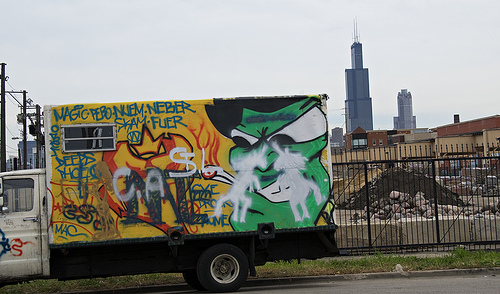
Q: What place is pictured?
A: It is a city.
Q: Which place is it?
A: It is a city.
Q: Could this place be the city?
A: Yes, it is the city.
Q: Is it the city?
A: Yes, it is the city.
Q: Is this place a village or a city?
A: It is a city.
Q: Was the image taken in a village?
A: No, the picture was taken in a city.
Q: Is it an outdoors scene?
A: Yes, it is outdoors.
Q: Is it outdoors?
A: Yes, it is outdoors.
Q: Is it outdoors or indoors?
A: It is outdoors.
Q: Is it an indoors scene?
A: No, it is outdoors.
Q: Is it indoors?
A: No, it is outdoors.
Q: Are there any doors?
A: Yes, there is a door.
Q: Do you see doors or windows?
A: Yes, there is a door.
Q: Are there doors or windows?
A: Yes, there is a door.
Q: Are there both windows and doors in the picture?
A: Yes, there are both a door and windows.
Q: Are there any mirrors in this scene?
A: No, there are no mirrors.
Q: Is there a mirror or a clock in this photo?
A: No, there are no mirrors or clocks.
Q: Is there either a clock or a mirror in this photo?
A: No, there are no mirrors or clocks.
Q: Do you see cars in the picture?
A: No, there are no cars.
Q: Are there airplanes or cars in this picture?
A: No, there are no cars or airplanes.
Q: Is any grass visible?
A: Yes, there is grass.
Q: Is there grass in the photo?
A: Yes, there is grass.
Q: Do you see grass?
A: Yes, there is grass.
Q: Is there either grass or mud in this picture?
A: Yes, there is grass.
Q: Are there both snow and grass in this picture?
A: No, there is grass but no snow.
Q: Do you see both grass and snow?
A: No, there is grass but no snow.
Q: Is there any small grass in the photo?
A: Yes, there is small grass.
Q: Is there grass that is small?
A: Yes, there is grass that is small.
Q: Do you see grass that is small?
A: Yes, there is grass that is small.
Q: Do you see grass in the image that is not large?
A: Yes, there is small grass.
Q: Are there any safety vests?
A: No, there are no safety vests.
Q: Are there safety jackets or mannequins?
A: No, there are no safety jackets or mannequins.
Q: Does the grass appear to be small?
A: Yes, the grass is small.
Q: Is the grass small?
A: Yes, the grass is small.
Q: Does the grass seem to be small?
A: Yes, the grass is small.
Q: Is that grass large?
A: No, the grass is small.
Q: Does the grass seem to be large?
A: No, the grass is small.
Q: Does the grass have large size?
A: No, the grass is small.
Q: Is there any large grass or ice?
A: No, there is grass but it is small.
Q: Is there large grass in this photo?
A: No, there is grass but it is small.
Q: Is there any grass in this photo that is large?
A: No, there is grass but it is small.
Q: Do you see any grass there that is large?
A: No, there is grass but it is small.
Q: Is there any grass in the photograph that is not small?
A: No, there is grass but it is small.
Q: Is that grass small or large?
A: The grass is small.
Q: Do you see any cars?
A: No, there are no cars.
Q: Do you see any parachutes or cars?
A: No, there are no cars or parachutes.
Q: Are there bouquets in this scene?
A: No, there are no bouquets.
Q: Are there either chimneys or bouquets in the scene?
A: No, there are no bouquets or chimneys.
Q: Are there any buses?
A: No, there are no buses.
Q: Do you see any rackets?
A: No, there are no rackets.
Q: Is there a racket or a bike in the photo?
A: No, there are no rackets or bikes.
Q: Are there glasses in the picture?
A: No, there are no glasses.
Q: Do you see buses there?
A: No, there are no buses.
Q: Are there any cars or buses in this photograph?
A: No, there are no buses or cars.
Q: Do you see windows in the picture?
A: Yes, there is a window.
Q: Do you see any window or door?
A: Yes, there is a window.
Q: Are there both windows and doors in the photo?
A: Yes, there are both a window and a door.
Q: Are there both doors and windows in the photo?
A: Yes, there are both a window and a door.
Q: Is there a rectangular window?
A: Yes, there is a rectangular window.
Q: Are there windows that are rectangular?
A: Yes, there is a window that is rectangular.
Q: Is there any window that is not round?
A: Yes, there is a rectangular window.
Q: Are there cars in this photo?
A: No, there are no cars.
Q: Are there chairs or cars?
A: No, there are no cars or chairs.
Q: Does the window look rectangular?
A: Yes, the window is rectangular.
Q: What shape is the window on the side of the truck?
A: The window is rectangular.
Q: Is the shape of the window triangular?
A: No, the window is rectangular.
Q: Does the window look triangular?
A: No, the window is rectangular.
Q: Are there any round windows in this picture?
A: No, there is a window but it is rectangular.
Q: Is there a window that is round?
A: No, there is a window but it is rectangular.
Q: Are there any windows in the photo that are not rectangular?
A: No, there is a window but it is rectangular.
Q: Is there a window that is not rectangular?
A: No, there is a window but it is rectangular.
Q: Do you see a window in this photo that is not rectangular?
A: No, there is a window but it is rectangular.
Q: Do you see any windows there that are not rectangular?
A: No, there is a window but it is rectangular.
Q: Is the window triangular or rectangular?
A: The window is rectangular.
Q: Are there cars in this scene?
A: No, there are no cars.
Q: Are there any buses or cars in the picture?
A: No, there are no cars or buses.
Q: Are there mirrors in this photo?
A: No, there are no mirrors.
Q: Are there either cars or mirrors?
A: No, there are no mirrors or cars.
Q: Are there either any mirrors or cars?
A: No, there are no mirrors or cars.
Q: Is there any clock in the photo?
A: No, there are no clocks.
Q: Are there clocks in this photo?
A: No, there are no clocks.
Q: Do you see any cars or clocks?
A: No, there are no clocks or cars.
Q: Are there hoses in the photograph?
A: No, there are no hoses.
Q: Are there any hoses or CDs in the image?
A: No, there are no hoses or cds.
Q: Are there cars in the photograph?
A: No, there are no cars.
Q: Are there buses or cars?
A: No, there are no cars or buses.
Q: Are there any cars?
A: No, there are no cars.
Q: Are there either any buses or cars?
A: No, there are no cars or buses.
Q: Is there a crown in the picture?
A: Yes, there is a crown.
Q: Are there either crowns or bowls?
A: Yes, there is a crown.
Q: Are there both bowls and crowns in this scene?
A: No, there is a crown but no bowls.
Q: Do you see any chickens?
A: No, there are no chickens.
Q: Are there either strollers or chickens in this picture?
A: No, there are no chickens or strollers.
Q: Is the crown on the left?
A: Yes, the crown is on the left of the image.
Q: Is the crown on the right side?
A: No, the crown is on the left of the image.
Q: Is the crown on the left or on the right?
A: The crown is on the left of the image.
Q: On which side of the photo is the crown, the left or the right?
A: The crown is on the left of the image.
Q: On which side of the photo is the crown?
A: The crown is on the left of the image.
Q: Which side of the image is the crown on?
A: The crown is on the left of the image.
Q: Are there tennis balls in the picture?
A: No, there are no tennis balls.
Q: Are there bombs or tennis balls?
A: No, there are no tennis balls or bombs.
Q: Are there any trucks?
A: Yes, there is a truck.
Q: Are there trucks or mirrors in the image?
A: Yes, there is a truck.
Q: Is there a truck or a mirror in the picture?
A: Yes, there is a truck.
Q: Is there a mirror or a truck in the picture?
A: Yes, there is a truck.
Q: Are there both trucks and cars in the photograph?
A: No, there is a truck but no cars.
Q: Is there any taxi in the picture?
A: No, there are no taxis.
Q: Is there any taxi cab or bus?
A: No, there are no taxis or buses.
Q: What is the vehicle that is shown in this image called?
A: The vehicle is a truck.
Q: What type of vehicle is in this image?
A: The vehicle is a truck.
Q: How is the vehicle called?
A: The vehicle is a truck.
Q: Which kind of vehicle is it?
A: The vehicle is a truck.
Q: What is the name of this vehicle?
A: This is a truck.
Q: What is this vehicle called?
A: This is a truck.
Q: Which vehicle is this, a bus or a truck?
A: This is a truck.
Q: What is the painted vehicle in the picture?
A: The vehicle is a truck.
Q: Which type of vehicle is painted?
A: The vehicle is a truck.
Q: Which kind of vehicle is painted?
A: The vehicle is a truck.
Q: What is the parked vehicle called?
A: The vehicle is a truck.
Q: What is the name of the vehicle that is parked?
A: The vehicle is a truck.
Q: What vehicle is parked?
A: The vehicle is a truck.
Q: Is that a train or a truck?
A: That is a truck.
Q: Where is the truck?
A: The truck is on the road.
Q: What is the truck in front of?
A: The truck is in front of the building.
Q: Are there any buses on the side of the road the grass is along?
A: No, there is a truck on the side of the road.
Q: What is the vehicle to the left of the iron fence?
A: The vehicle is a truck.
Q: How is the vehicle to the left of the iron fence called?
A: The vehicle is a truck.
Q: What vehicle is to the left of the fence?
A: The vehicle is a truck.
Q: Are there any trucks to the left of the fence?
A: Yes, there is a truck to the left of the fence.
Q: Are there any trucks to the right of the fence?
A: No, the truck is to the left of the fence.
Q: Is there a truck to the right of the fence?
A: No, the truck is to the left of the fence.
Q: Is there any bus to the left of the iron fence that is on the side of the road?
A: No, there is a truck to the left of the fence.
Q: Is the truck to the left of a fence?
A: Yes, the truck is to the left of a fence.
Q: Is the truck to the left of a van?
A: No, the truck is to the left of a fence.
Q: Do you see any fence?
A: Yes, there is a fence.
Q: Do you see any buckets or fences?
A: Yes, there is a fence.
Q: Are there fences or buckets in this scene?
A: Yes, there is a fence.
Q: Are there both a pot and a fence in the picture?
A: No, there is a fence but no pots.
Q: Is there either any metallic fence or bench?
A: Yes, there is a metal fence.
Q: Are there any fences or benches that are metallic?
A: Yes, the fence is metallic.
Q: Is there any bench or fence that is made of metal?
A: Yes, the fence is made of metal.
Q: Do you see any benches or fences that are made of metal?
A: Yes, the fence is made of metal.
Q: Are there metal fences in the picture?
A: Yes, there is a metal fence.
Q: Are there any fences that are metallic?
A: Yes, there is a fence that is metallic.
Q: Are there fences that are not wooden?
A: Yes, there is a metallic fence.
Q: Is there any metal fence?
A: Yes, there is a fence that is made of metal.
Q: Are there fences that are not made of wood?
A: Yes, there is a fence that is made of metal.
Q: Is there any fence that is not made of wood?
A: Yes, there is a fence that is made of metal.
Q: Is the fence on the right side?
A: Yes, the fence is on the right of the image.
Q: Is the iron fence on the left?
A: No, the fence is on the right of the image.